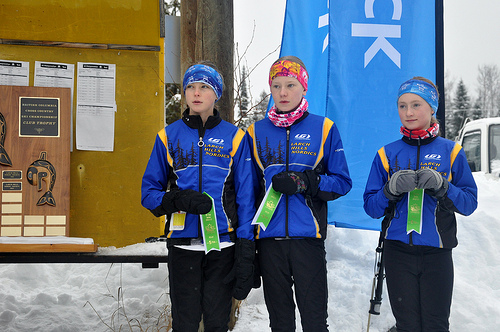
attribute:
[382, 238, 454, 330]
pants — blue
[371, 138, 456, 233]
jacket — blue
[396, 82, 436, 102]
headband — blue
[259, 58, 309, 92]
headband — pink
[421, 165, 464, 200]
glove — grey, winter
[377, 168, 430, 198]
glove — grey, winter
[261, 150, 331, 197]
glove — grey, winter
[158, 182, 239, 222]
glove — grey, winter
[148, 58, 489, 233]
three girls — skiing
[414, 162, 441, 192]
hand — girl's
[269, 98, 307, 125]
scarf — pink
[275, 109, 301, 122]
neck — girl's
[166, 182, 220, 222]
mitten — black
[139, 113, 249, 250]
winter jacket — black, white, blue, yellow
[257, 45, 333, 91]
bandanna — orange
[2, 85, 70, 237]
plaque — commemorative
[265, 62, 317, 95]
headband — pink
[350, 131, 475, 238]
jacket — blue, ski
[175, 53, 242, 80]
headband — blue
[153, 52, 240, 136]
head — girl's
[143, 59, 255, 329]
skiers — young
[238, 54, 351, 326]
skiers — young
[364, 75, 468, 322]
skiers — young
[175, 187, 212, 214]
hand — girl's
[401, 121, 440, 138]
scarf — red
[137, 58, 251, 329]
skier — young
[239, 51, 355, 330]
skier — young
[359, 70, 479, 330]
skier — young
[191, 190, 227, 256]
ribbon — green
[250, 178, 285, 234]
ribbon — green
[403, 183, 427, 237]
ribbon — green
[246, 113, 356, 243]
jacket — blue, ski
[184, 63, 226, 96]
bandana — blue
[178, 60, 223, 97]
headband — blue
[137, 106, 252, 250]
jacket — blue, ski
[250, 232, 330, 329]
pants — blue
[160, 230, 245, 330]
pants — blue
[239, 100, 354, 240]
jacket — blue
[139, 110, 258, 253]
jacket — blue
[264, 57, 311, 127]
head — girl's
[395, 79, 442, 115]
headband — blue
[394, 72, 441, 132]
head — girl's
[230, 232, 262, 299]
mitten — black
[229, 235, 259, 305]
hand — girl's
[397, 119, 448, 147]
neck — girl's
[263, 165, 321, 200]
hand — girl's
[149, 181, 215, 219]
hand — girl's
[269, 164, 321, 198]
hand — girl's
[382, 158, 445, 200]
hand — girl's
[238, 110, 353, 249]
jacket — black, white, blue, yellow, winter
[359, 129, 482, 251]
jacket — blue, black, white, yellow, winter